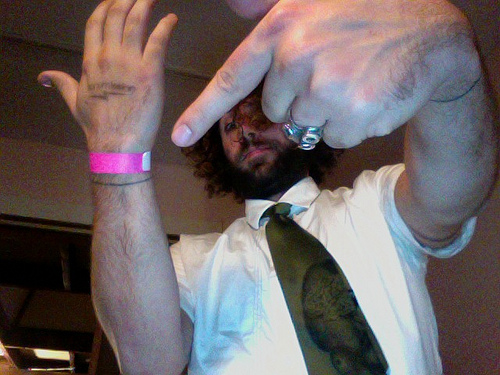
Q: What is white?
A: Man's shirt.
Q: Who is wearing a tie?
A: A man.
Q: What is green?
A: Tie.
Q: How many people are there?
A: One.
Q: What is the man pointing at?
A: Pink bracelet.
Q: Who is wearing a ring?
A: Man.